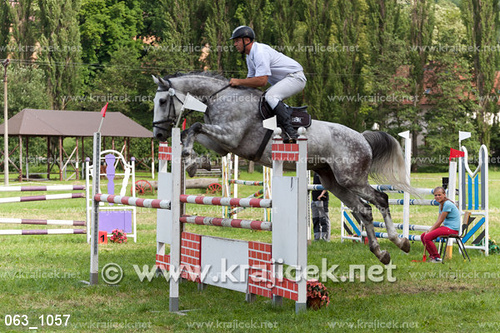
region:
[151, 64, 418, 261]
it is a black color horse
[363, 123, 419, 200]
it is a horse tail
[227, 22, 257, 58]
man wearing helmet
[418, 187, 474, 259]
woman sitting on the chair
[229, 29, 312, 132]
man wearing white color shirt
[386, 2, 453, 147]
it is a tree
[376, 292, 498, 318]
it is green grass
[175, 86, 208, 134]
white color flag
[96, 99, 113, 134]
it is red color flag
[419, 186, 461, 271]
woman wearing red color pant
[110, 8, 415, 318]
Man riding a race horse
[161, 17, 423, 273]
Man riding a gray horse at a race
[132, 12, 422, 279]
Man wearing a helmet and riding a race horse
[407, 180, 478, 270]
Lady wearing red pants sitting on a chair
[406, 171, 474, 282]
Lady sitting on a chair on a lawn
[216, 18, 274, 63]
Man wearing a black helmet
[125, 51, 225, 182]
Gray horse with harness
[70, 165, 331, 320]
Horse race field red and white bars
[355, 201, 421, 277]
Horse's hind legs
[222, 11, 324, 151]
Man wearing a white horse racing outfit with a black helmet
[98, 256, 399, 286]
Website watermark marking image ownership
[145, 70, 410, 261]
dapple grey horse leaping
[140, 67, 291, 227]
horse jumping over hurdle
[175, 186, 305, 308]
red and white horse hurdles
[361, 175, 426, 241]
blue and white horse hurdles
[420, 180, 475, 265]
girl watching horse perform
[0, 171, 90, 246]
purple and white horse hurdles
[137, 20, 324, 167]
man riding a horse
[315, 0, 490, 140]
trees obscuring view into horse training area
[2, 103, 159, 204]
shade covering in the background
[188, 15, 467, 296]
the man is riding a horse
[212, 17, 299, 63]
the man is wearing a helmet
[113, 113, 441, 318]
the horse is jumping hurdles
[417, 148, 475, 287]
the woman is sitting in a chair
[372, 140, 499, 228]
the woman is watching the horse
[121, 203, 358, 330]
the brick is red and white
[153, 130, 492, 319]
the wooden poles are white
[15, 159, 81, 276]
the poles are red and white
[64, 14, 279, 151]
the trees are in the background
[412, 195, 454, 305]
the girl is wearing red pants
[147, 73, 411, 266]
white and gray horse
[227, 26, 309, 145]
man riding horse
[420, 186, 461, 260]
girl sitting in a chair behind the horse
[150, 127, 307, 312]
barrier the horse is jumping that has bricks painted on it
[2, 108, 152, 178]
brown awning in the background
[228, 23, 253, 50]
black helmet worn by the rider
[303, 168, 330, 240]
person standing by a barrier behind the horse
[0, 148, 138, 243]
barrier with purple and white on its end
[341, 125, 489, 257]
barrier decorated with blue and gray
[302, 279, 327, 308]
pink flowers near the barrier the horse is jumping over